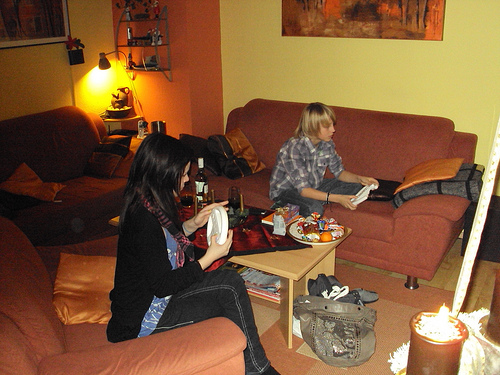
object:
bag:
[289, 294, 379, 368]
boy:
[268, 100, 381, 221]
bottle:
[190, 157, 210, 214]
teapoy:
[186, 187, 255, 220]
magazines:
[234, 267, 280, 303]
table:
[107, 199, 354, 352]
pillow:
[45, 234, 120, 330]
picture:
[278, 0, 449, 42]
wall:
[217, 0, 497, 202]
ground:
[334, 229, 497, 335]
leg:
[402, 269, 423, 291]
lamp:
[90, 45, 130, 74]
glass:
[227, 184, 240, 211]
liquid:
[227, 197, 243, 209]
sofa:
[186, 97, 479, 293]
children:
[105, 101, 383, 373]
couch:
[0, 103, 148, 250]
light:
[67, 50, 136, 105]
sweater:
[103, 193, 206, 342]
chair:
[1, 212, 248, 371]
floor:
[233, 233, 498, 373]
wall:
[1, 0, 225, 139]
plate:
[288, 216, 351, 246]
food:
[295, 211, 347, 244]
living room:
[2, 0, 499, 372]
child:
[109, 132, 285, 375]